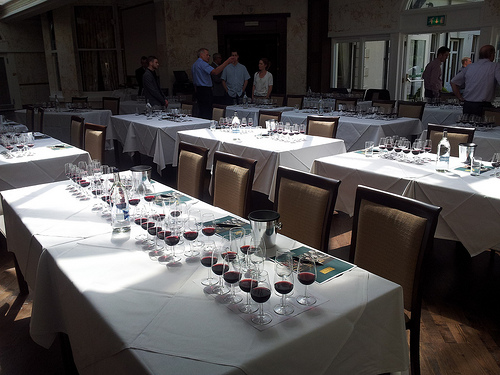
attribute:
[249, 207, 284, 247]
container — silver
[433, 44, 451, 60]
hair — short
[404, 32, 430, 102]
door — white 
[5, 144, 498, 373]
floor — brown, hardwood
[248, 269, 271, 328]
glass — clean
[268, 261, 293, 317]
glass — clear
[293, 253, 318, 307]
glass — new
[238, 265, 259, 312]
glass — closest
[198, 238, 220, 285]
glass — last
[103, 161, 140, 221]
wine glasses — clear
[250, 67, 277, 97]
shirt — white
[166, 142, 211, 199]
chair — empty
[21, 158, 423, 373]
tablecloth — white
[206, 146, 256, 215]
chair — empty 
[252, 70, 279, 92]
shirt — white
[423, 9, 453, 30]
sign — green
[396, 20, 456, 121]
door — open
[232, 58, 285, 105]
shirt — light blue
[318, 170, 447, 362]
chair — brown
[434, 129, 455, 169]
bottle — glass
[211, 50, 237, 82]
arm — extended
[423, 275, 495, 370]
floor — wooden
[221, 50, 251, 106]
man — tall, short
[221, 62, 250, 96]
blue shirt — dark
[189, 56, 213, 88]
blue shirt — light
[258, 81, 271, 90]
shirt — clean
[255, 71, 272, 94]
shirt — white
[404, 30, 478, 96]
wall — painted, white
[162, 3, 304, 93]
wall — painted, white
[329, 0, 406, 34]
wall — painted, white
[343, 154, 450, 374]
chair — empty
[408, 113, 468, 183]
wine — tall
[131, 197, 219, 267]
wine glasses — unique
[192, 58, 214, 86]
shirt — blue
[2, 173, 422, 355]
cloth — white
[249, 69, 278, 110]
woman — nearby